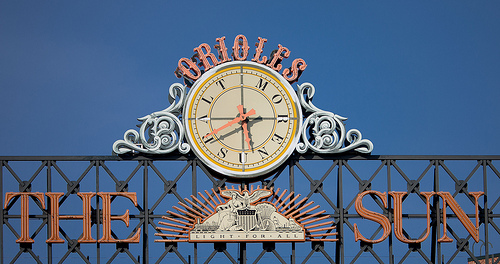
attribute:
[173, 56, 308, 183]
clock — metal, large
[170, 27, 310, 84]
orioles — orange, large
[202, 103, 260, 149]
hands — orange, neon red, neon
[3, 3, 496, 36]
sky — blue, dark blue, clear, very blue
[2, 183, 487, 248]
words — the sun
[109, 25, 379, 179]
sign — white, orange, metal